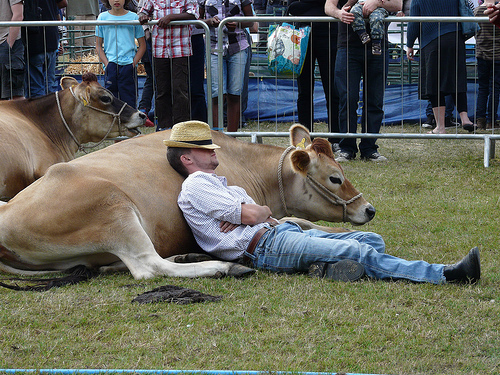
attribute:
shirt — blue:
[92, 8, 151, 64]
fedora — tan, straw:
[162, 118, 224, 152]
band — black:
[176, 136, 216, 147]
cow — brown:
[0, 55, 178, 197]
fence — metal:
[209, 5, 494, 168]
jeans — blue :
[258, 211, 478, 312]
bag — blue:
[266, 20, 311, 79]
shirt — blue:
[89, 7, 154, 71]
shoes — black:
[442, 238, 487, 290]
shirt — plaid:
[184, 173, 272, 255]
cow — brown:
[0, 75, 147, 210]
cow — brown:
[0, 123, 377, 290]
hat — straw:
[147, 117, 237, 160]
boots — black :
[434, 236, 484, 290]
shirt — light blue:
[178, 164, 282, 261]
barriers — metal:
[2, 13, 484, 165]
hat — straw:
[164, 110, 220, 150]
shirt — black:
[407, 0, 480, 42]